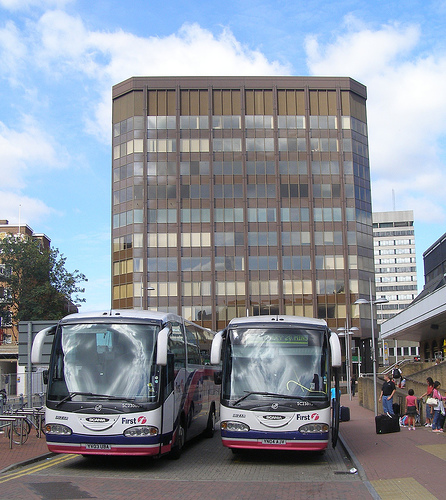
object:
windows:
[111, 114, 381, 336]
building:
[110, 70, 446, 418]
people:
[378, 374, 395, 415]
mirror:
[30, 326, 56, 364]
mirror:
[328, 332, 343, 368]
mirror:
[210, 327, 223, 364]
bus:
[30, 309, 222, 461]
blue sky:
[0, 1, 445, 34]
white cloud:
[0, 126, 73, 180]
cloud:
[0, 0, 444, 171]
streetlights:
[352, 297, 390, 304]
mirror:
[155, 325, 172, 365]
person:
[406, 387, 419, 430]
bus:
[209, 314, 340, 455]